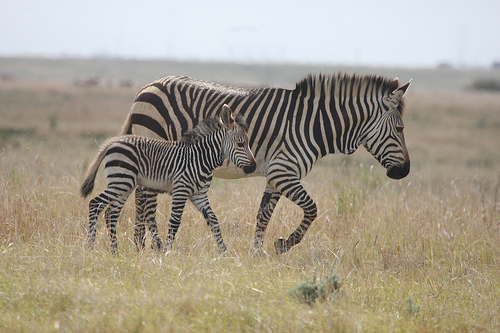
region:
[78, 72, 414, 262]
Zebra mare and foal on grassy plain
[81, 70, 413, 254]
Two zebras walking in tall brown grass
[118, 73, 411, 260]
Adult zebra with dewlap on neck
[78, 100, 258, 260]
Very young zebra foal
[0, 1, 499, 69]
Hazy blue sky above horizon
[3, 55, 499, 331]
Undulating plain of tall grass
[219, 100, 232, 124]
Large ear of baby zebra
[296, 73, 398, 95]
Black and white striped upright mane of adult zebra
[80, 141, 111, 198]
Short brushy tail of zebra foal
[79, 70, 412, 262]
Female zebra with offspring on savannah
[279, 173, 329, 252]
leg of a zebra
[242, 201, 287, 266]
leg of a zebra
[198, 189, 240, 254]
leg of a zebra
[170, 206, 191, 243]
leg of a zebra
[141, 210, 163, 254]
leg of a zebra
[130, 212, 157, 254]
leg of a zebra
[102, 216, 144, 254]
leg of a zebra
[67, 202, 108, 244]
leg of a zebra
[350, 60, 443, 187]
head of a zebra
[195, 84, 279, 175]
head of a zebra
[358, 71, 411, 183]
the head of a zebra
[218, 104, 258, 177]
the head of a zebra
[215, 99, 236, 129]
the ear of a zebra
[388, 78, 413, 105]
the ear of a zebra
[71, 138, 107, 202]
the tail of a zebra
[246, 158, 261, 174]
the nose of a zebra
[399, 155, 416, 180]
the nose of a zebra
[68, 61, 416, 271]
a baby zebra walking with a mother zebra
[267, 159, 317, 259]
the front leg of a zebra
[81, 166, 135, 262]
the hind legs of a zebra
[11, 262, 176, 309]
tall grass in the field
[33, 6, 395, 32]
the sky in the background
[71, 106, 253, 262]
a baby zebra on the scene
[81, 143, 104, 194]
the tail of the baby zebra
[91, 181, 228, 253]
the four legs of the zebra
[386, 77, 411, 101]
the two ears of the zebra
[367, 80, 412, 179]
the head of the zebra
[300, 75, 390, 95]
the beautiful mane of the zebra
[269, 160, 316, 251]
this leg is raised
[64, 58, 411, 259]
two zebras on the scene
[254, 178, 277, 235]
leg of a zebra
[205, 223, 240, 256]
leg of a zebra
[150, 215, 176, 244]
leg of a zebra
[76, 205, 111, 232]
leg of a zebra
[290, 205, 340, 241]
a leg of a zebra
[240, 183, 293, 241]
a leg of a zebra